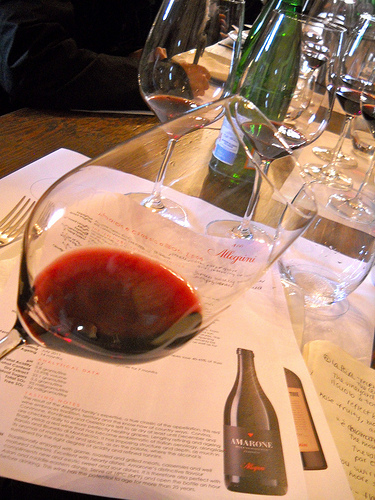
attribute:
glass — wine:
[1, 97, 318, 364]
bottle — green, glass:
[206, 0, 307, 196]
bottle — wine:
[241, 15, 287, 94]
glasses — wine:
[120, 6, 374, 261]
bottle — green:
[212, 0, 304, 193]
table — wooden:
[0, 29, 373, 266]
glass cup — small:
[278, 176, 373, 309]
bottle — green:
[184, 7, 302, 225]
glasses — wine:
[133, 2, 237, 244]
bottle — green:
[215, 38, 297, 190]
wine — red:
[20, 245, 204, 360]